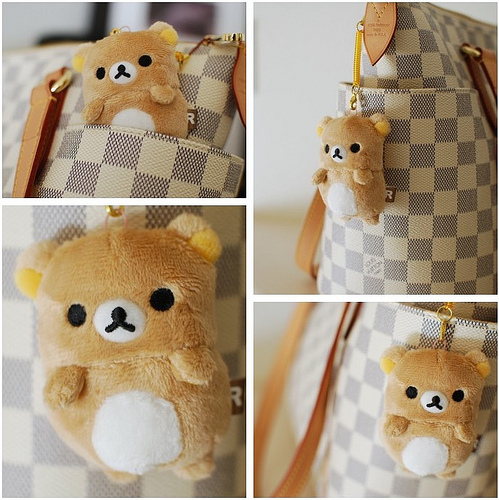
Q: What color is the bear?
A: Brown.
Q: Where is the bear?
A: Attached to a bag.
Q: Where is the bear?
A: Inside the pocket.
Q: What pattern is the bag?
A: Checkered.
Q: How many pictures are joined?
A: Four.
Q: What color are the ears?
A: Yellow.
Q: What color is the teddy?
A: Brown.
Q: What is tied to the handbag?
A: Teddy.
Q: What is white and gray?
A: Handbag.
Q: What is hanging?
A: Stuffed bear.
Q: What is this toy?
A: A stuffed animal.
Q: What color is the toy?
A: Brown and white.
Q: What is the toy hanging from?
A: A bag.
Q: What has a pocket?
A: The bag.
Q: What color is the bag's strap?
A: Tan.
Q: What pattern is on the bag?
A: Checks.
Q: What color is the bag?
A: White and grey.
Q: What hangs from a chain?
A: The toy.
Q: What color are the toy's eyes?
A: Black.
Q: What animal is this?
A: Bear.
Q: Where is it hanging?
A: On a bag.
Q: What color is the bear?
A: Tan.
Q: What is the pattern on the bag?
A: Checkered.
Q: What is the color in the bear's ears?
A: Yellow.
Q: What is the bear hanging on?
A: Bag.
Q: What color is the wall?
A: White.